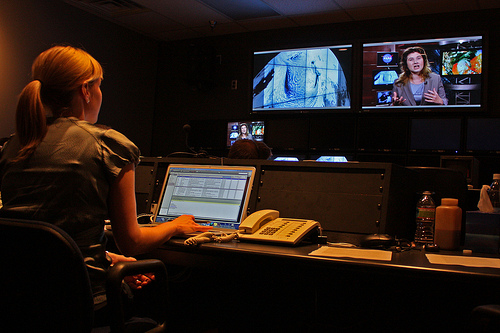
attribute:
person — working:
[24, 38, 184, 330]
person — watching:
[0, 29, 187, 330]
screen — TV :
[251, 52, 484, 102]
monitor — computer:
[153, 165, 236, 225]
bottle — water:
[414, 189, 440, 257]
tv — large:
[255, 40, 485, 110]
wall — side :
[191, 65, 247, 120]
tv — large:
[246, 47, 364, 116]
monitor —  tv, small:
[228, 119, 262, 141]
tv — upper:
[247, 48, 343, 106]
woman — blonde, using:
[0, 48, 181, 318]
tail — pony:
[14, 87, 46, 146]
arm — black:
[131, 251, 170, 283]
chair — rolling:
[3, 221, 151, 331]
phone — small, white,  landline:
[233, 206, 314, 256]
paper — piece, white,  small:
[317, 245, 393, 265]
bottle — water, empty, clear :
[413, 186, 437, 258]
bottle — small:
[433, 197, 464, 257]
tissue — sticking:
[470, 181, 484, 200]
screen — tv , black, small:
[248, 57, 358, 110]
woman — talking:
[402, 55, 446, 114]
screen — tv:
[369, 48, 478, 103]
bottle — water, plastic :
[418, 188, 437, 258]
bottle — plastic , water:
[406, 191, 436, 253]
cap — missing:
[454, 242, 473, 256]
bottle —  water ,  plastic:
[445, 185, 462, 239]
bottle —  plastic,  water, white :
[470, 185, 476, 217]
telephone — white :
[233, 196, 312, 249]